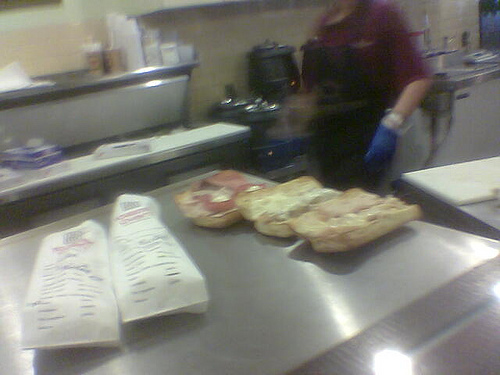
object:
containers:
[121, 17, 148, 71]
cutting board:
[401, 152, 500, 207]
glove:
[364, 114, 406, 171]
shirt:
[301, 0, 435, 124]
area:
[0, 120, 248, 209]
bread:
[288, 186, 425, 252]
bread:
[175, 168, 268, 228]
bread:
[234, 175, 344, 238]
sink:
[425, 46, 500, 83]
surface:
[1, 168, 497, 373]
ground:
[371, 161, 430, 202]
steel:
[204, 232, 499, 369]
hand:
[359, 127, 404, 168]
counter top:
[0, 120, 249, 192]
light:
[370, 342, 416, 374]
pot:
[246, 38, 302, 102]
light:
[287, 237, 362, 340]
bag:
[19, 217, 123, 352]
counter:
[0, 169, 499, 374]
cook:
[277, 0, 435, 195]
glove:
[248, 125, 312, 173]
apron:
[305, 0, 390, 193]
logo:
[347, 37, 376, 49]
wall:
[151, 4, 485, 114]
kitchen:
[10, 9, 499, 374]